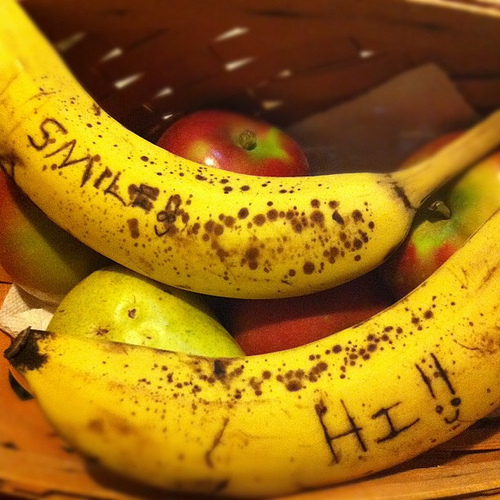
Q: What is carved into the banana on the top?
A: Smile.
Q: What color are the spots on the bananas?
A: Brown.